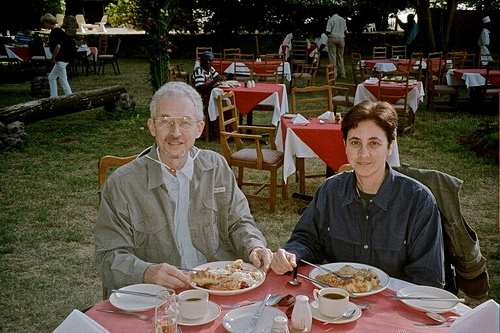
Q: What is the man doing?
A: Sitting.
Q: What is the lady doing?
A: Sitting.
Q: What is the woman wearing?
A: Blue shirt.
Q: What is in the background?
A: Wooden chair.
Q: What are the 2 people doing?
A: Eating breakfast.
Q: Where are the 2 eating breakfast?
A: Outdoors area.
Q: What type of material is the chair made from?
A: Wood.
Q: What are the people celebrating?
A: Wedding.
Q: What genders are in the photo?
A: Male and female.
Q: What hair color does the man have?
A: White.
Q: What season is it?
A: Fall.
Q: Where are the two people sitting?
A: Table.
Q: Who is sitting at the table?
A: A man and woman.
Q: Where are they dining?
A: At an outdoor spot.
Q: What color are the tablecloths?
A: Red and white.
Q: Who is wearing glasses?
A: The man.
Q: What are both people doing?
A: Smiling.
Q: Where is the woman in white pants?
A: Behind a log.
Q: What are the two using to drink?
A: Coffee cups.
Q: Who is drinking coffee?
A: Both of them.